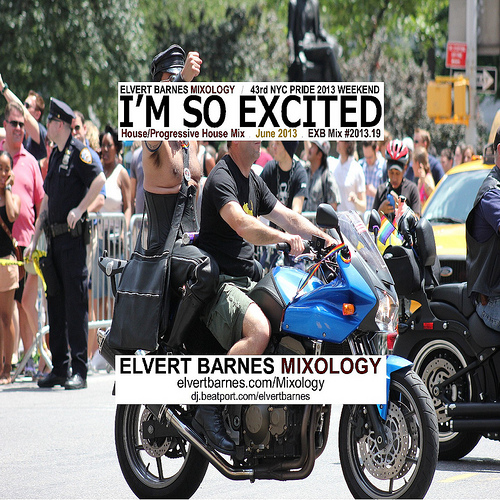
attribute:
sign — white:
[117, 79, 389, 146]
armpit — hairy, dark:
[147, 142, 166, 166]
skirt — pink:
[0, 255, 19, 292]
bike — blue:
[111, 207, 440, 499]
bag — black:
[107, 248, 169, 353]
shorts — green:
[197, 275, 256, 355]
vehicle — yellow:
[381, 156, 495, 261]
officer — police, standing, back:
[38, 96, 105, 392]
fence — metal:
[87, 210, 150, 327]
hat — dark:
[49, 98, 74, 126]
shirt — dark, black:
[43, 138, 102, 222]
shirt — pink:
[1, 142, 45, 251]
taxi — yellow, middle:
[376, 153, 495, 283]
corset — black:
[137, 183, 203, 263]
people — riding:
[124, 42, 339, 450]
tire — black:
[115, 385, 212, 500]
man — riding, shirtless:
[378, 135, 426, 213]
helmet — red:
[386, 143, 409, 171]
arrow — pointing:
[459, 67, 500, 92]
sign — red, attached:
[444, 40, 469, 71]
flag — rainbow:
[296, 241, 350, 288]